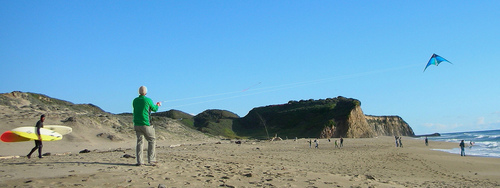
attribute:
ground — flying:
[338, 112, 350, 162]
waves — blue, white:
[428, 132, 498, 153]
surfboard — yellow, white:
[8, 122, 68, 144]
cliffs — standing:
[240, 95, 415, 137]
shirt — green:
[130, 96, 172, 126]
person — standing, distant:
[458, 138, 469, 158]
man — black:
[25, 114, 45, 159]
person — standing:
[455, 132, 472, 158]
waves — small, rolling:
[465, 130, 498, 150]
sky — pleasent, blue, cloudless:
[222, 6, 406, 96]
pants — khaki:
[136, 125, 157, 165]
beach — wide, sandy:
[228, 141, 405, 183]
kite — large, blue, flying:
[422, 47, 458, 78]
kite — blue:
[421, 50, 458, 73]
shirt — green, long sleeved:
[132, 97, 159, 125]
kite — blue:
[423, 50, 453, 70]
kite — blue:
[425, 50, 446, 69]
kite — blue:
[420, 52, 447, 70]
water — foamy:
[359, 98, 490, 188]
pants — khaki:
[132, 124, 164, 188]